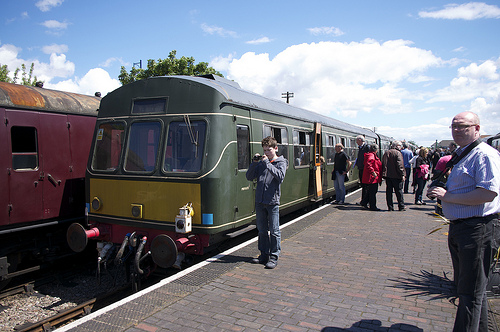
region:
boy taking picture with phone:
[253, 132, 287, 264]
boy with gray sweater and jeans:
[240, 134, 297, 267]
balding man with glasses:
[428, 115, 498, 329]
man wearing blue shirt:
[428, 111, 491, 328]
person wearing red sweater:
[354, 139, 389, 210]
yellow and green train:
[68, 65, 428, 263]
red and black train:
[1, 77, 117, 243]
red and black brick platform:
[51, 177, 496, 330]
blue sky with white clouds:
[2, 0, 498, 119]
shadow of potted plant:
[387, 240, 472, 309]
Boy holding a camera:
[244, 132, 288, 268]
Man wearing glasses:
[418, 102, 498, 329]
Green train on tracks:
[67, 76, 415, 278]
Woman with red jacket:
[359, 138, 381, 213]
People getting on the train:
[321, 127, 471, 212]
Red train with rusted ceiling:
[0, 78, 104, 289]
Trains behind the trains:
[0, 47, 237, 96]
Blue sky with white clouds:
[1, 2, 498, 127]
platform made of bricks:
[64, 162, 499, 330]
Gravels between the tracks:
[1, 282, 78, 327]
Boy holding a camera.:
[220, 70, 317, 302]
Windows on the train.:
[73, 97, 284, 212]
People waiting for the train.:
[317, 102, 480, 234]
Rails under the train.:
[36, 270, 204, 319]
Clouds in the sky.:
[17, 38, 153, 109]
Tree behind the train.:
[109, 37, 281, 139]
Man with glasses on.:
[409, 97, 494, 163]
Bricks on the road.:
[237, 230, 332, 330]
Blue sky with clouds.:
[48, 42, 373, 138]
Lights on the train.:
[82, 192, 215, 275]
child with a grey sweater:
[236, 121, 307, 272]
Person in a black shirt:
[320, 134, 355, 217]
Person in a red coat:
[354, 139, 393, 214]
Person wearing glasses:
[422, 102, 498, 330]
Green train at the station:
[52, 58, 446, 260]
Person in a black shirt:
[410, 141, 437, 209]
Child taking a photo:
[236, 123, 295, 270]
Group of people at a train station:
[326, 128, 466, 211]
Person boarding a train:
[325, 140, 353, 210]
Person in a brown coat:
[382, 137, 411, 219]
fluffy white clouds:
[213, 39, 472, 108]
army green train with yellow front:
[85, 67, 395, 235]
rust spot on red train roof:
[0, 95, 98, 162]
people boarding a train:
[311, 127, 412, 202]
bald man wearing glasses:
[431, 117, 498, 249]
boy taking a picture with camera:
[249, 138, 299, 268]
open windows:
[261, 119, 333, 155]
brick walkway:
[219, 203, 434, 322]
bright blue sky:
[70, 12, 308, 39]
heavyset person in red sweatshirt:
[363, 138, 381, 205]